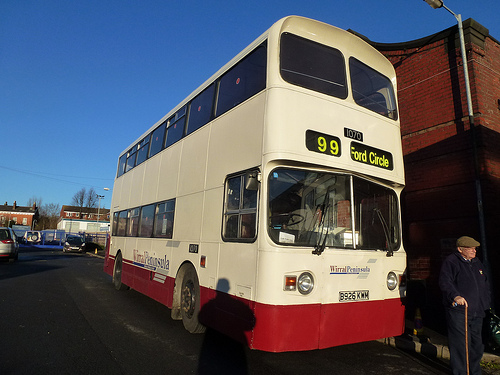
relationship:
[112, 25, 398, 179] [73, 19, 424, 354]
windows on top of bus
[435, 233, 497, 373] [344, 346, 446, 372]
man walking down street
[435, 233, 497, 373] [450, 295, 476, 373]
man walking with cane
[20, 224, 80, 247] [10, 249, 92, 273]
cars parked at end of road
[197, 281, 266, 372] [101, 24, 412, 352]
shadow on bus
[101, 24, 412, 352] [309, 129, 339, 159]
bus has number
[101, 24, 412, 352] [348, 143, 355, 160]
bus has letter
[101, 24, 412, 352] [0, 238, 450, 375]
bus on road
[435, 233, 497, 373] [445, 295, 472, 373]
man walking with cane